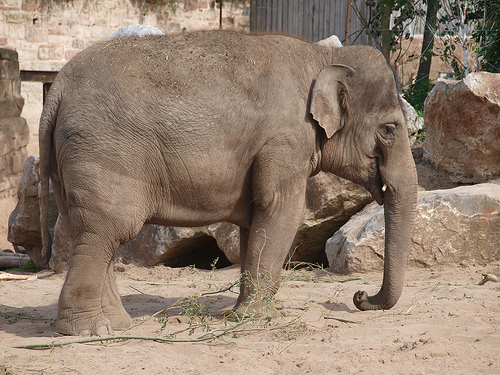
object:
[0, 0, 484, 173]
wall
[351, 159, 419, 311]
trunk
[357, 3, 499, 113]
tree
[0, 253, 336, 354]
stick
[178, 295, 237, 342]
leaves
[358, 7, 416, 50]
leaf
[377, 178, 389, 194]
tusk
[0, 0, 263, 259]
building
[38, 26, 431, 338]
train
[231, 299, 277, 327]
hoof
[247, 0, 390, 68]
fence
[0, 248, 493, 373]
sand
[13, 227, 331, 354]
branch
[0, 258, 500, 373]
ground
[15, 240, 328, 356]
twig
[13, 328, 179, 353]
tree limb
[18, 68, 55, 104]
post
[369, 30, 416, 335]
elephant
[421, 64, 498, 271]
tan rocks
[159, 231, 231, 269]
hole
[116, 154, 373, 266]
rocks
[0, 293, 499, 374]
sand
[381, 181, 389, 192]
stick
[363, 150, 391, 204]
mouth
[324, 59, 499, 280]
boulders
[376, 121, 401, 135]
eye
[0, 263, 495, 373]
dirt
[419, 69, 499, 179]
rock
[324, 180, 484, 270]
rock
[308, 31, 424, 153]
rock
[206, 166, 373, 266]
rock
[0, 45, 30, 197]
rock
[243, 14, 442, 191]
metal shed